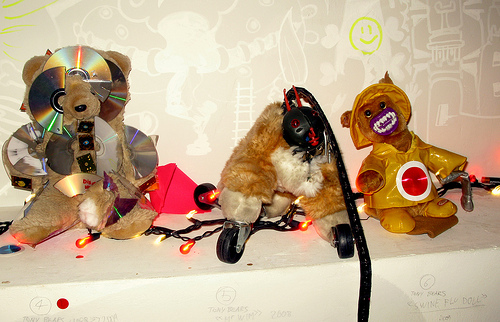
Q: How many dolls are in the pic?
A: Three.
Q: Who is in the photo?
A: No one.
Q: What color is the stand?
A: White.